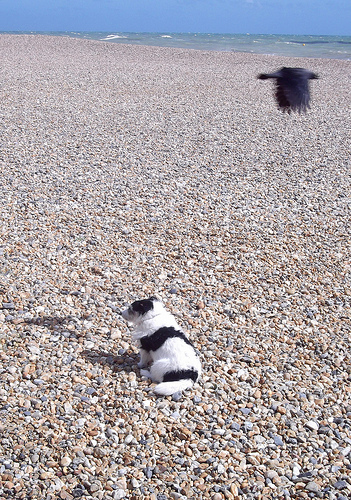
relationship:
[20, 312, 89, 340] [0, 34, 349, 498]
shadow on ground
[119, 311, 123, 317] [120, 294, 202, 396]
nose of black/white dog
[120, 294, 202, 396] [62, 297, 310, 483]
black/white dog on rocks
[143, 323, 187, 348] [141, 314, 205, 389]
black stripe on dog's back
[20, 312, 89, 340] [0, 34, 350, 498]
shadow on rocks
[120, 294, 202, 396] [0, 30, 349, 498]
black/white dog on beach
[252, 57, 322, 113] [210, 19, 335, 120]
bird in air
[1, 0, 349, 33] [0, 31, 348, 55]
sky above water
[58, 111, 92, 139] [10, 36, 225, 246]
rocks on ground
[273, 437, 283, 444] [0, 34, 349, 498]
pebble visible on ground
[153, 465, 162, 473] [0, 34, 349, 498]
pebble visible on ground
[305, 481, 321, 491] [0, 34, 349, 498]
pebble visible on ground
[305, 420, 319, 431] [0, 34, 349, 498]
pebble visible on ground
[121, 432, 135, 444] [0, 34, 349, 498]
pebble visible on ground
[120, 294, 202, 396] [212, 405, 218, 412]
black/white dog laying in rocks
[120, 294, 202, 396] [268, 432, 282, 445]
black/white dog laying in rocks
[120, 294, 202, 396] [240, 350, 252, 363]
black/white dog laying in rocks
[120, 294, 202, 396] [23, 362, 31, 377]
black/white dog laying in rocks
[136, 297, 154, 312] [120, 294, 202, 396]
ear of black/white dog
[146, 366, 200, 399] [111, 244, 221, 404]
tail of a dog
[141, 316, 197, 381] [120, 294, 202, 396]
coat of a black/white dog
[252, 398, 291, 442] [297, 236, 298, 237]
part of a ground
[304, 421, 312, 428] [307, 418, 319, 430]
part of a stone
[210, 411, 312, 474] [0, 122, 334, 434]
part of a ground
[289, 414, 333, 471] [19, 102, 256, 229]
part of a ground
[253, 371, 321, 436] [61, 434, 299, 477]
part of a floor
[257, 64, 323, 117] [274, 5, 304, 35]
bird flying in air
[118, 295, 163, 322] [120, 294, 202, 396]
head of black/white dog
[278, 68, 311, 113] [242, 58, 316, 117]
wings of bird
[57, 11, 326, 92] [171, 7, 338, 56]
sea in background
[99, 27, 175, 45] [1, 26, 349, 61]
ripples in sea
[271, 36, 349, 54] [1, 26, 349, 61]
ripples in sea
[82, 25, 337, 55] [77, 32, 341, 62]
body of water